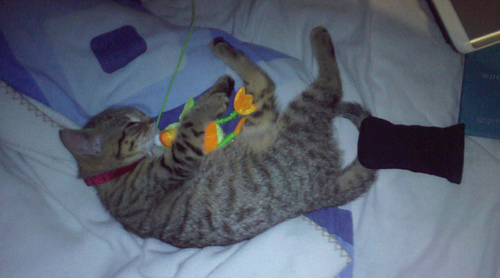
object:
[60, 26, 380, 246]
cat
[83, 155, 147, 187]
collar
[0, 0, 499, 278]
bed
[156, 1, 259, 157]
toy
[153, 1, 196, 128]
stick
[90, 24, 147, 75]
square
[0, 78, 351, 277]
blanket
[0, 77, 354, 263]
stitching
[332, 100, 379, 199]
tail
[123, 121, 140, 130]
eye